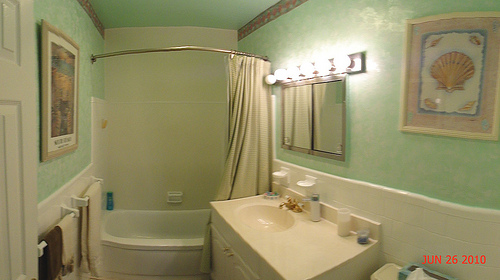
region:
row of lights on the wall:
[248, 52, 359, 87]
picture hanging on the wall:
[383, 15, 497, 147]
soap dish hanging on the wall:
[166, 188, 186, 203]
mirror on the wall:
[271, 74, 356, 167]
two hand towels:
[31, 213, 85, 279]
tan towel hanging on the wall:
[76, 179, 126, 273]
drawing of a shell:
[428, 49, 476, 98]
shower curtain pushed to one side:
[199, 48, 278, 278]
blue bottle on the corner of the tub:
[103, 187, 118, 212]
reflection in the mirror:
[284, 88, 311, 147]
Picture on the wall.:
[389, 12, 496, 149]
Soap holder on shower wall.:
[163, 188, 185, 207]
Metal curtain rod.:
[87, 40, 272, 68]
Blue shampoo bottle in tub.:
[100, 188, 120, 210]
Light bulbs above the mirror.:
[255, 48, 358, 84]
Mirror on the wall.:
[274, 76, 359, 162]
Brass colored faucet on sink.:
[275, 194, 301, 218]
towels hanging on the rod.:
[37, 205, 77, 279]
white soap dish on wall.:
[294, 168, 319, 195]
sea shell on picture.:
[425, 49, 476, 97]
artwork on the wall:
[36, 20, 86, 171]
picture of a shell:
[428, 50, 473, 95]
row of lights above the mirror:
[258, 55, 355, 85]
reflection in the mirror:
[278, 83, 346, 150]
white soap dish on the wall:
[163, 186, 183, 205]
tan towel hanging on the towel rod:
[75, 180, 116, 276]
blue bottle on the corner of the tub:
[106, 188, 115, 208]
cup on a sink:
[333, 208, 358, 230]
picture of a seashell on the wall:
[408, 19, 491, 134]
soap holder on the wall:
[161, 184, 186, 204]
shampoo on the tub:
[102, 188, 114, 208]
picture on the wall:
[33, 12, 82, 174]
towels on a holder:
[78, 180, 132, 278]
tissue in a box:
[392, 253, 438, 270]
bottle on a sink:
[306, 187, 325, 228]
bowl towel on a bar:
[36, 225, 73, 263]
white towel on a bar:
[73, 175, 128, 275]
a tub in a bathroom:
[93, 169, 227, 261]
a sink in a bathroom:
[215, 185, 336, 252]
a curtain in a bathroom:
[181, 48, 285, 180]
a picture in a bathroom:
[358, 21, 498, 152]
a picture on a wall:
[23, 9, 120, 161]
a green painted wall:
[350, 107, 405, 143]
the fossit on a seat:
[264, 184, 314, 221]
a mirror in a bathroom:
[211, 45, 416, 165]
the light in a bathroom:
[233, 38, 377, 154]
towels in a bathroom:
[48, 185, 122, 259]